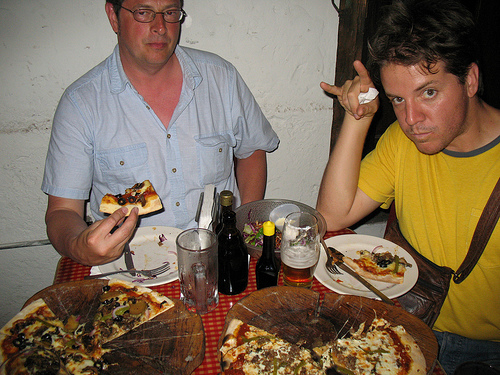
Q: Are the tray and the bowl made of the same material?
A: No, the tray is made of wood and the bowl is made of metal.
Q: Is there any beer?
A: Yes, there is beer.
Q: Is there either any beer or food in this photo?
A: Yes, there is beer.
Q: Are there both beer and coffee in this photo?
A: No, there is beer but no coffee.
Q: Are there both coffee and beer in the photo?
A: No, there is beer but no coffee.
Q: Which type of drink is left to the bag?
A: The drink is beer.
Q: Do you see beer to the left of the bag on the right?
A: Yes, there is beer to the left of the bag.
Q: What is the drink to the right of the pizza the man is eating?
A: The drink is beer.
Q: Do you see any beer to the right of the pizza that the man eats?
A: Yes, there is beer to the right of the pizza.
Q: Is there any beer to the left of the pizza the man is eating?
A: No, the beer is to the right of the pizza.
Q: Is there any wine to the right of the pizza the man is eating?
A: No, there is beer to the right of the pizza.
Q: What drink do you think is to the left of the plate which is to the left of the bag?
A: The drink is beer.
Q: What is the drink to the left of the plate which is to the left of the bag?
A: The drink is beer.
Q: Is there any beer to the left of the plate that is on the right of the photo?
A: Yes, there is beer to the left of the plate.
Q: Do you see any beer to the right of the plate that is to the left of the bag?
A: No, the beer is to the left of the plate.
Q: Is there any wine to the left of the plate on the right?
A: No, there is beer to the left of the plate.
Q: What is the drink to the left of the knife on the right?
A: The drink is beer.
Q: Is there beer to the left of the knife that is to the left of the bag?
A: Yes, there is beer to the left of the knife.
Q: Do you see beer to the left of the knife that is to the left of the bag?
A: Yes, there is beer to the left of the knife.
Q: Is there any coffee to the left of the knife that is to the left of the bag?
A: No, there is beer to the left of the knife.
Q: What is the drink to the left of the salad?
A: The drink is beer.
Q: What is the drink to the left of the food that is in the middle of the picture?
A: The drink is beer.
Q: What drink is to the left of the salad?
A: The drink is beer.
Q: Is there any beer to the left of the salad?
A: Yes, there is beer to the left of the salad.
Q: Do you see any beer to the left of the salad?
A: Yes, there is beer to the left of the salad.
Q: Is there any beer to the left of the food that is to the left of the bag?
A: Yes, there is beer to the left of the salad.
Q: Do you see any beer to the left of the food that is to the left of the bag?
A: Yes, there is beer to the left of the salad.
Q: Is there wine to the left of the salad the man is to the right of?
A: No, there is beer to the left of the salad.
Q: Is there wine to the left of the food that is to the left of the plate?
A: No, there is beer to the left of the salad.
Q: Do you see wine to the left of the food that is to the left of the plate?
A: No, there is beer to the left of the salad.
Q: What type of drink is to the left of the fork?
A: The drink is beer.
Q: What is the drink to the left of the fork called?
A: The drink is beer.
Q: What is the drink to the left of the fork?
A: The drink is beer.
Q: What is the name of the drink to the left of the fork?
A: The drink is beer.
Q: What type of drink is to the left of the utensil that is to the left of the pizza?
A: The drink is beer.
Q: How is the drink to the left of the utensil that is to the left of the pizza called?
A: The drink is beer.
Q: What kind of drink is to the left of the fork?
A: The drink is beer.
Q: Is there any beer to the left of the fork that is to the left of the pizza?
A: Yes, there is beer to the left of the fork.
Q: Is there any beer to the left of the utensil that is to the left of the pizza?
A: Yes, there is beer to the left of the fork.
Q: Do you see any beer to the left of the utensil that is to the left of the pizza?
A: Yes, there is beer to the left of the fork.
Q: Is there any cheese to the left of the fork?
A: No, there is beer to the left of the fork.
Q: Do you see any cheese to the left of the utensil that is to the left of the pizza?
A: No, there is beer to the left of the fork.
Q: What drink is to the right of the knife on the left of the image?
A: The drink is beer.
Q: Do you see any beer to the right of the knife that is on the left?
A: Yes, there is beer to the right of the knife.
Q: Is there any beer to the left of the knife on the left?
A: No, the beer is to the right of the knife.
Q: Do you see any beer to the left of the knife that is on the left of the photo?
A: No, the beer is to the right of the knife.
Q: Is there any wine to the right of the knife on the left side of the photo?
A: No, there is beer to the right of the knife.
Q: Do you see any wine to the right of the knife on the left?
A: No, there is beer to the right of the knife.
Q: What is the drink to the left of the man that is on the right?
A: The drink is beer.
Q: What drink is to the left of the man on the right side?
A: The drink is beer.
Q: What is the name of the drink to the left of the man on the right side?
A: The drink is beer.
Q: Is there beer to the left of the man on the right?
A: Yes, there is beer to the left of the man.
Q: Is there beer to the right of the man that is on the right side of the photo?
A: No, the beer is to the left of the man.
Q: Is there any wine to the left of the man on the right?
A: No, there is beer to the left of the man.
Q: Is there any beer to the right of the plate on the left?
A: Yes, there is beer to the right of the plate.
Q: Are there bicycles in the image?
A: No, there are no bicycles.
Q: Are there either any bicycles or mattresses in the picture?
A: No, there are no bicycles or mattresses.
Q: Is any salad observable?
A: Yes, there is salad.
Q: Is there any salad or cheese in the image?
A: Yes, there is salad.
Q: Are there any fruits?
A: No, there are no fruits.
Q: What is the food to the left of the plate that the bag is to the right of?
A: The food is salad.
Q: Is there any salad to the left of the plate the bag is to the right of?
A: Yes, there is salad to the left of the plate.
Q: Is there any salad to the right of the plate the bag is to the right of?
A: No, the salad is to the left of the plate.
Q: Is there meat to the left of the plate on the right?
A: No, there is salad to the left of the plate.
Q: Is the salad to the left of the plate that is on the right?
A: Yes, the salad is to the left of the plate.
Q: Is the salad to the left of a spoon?
A: No, the salad is to the left of the plate.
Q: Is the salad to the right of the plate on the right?
A: No, the salad is to the left of the plate.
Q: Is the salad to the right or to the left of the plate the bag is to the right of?
A: The salad is to the left of the plate.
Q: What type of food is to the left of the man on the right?
A: The food is salad.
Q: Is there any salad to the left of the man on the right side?
A: Yes, there is salad to the left of the man.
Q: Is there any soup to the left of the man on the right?
A: No, there is salad to the left of the man.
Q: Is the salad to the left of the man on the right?
A: Yes, the salad is to the left of the man.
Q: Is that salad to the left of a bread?
A: No, the salad is to the left of the man.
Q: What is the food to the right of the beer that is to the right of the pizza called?
A: The food is salad.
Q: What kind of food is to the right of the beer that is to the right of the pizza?
A: The food is salad.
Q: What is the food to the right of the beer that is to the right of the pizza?
A: The food is salad.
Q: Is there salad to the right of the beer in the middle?
A: Yes, there is salad to the right of the beer.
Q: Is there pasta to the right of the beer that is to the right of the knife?
A: No, there is salad to the right of the beer.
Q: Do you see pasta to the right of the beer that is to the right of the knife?
A: No, there is salad to the right of the beer.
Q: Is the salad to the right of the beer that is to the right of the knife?
A: Yes, the salad is to the right of the beer.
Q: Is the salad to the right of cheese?
A: No, the salad is to the right of the beer.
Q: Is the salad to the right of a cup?
A: No, the salad is to the right of the plate.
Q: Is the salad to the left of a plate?
A: No, the salad is to the right of a plate.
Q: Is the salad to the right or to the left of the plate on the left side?
A: The salad is to the right of the plate.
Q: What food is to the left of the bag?
A: The food is salad.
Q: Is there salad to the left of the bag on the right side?
A: Yes, there is salad to the left of the bag.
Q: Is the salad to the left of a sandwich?
A: No, the salad is to the left of the bag.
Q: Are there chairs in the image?
A: No, there are no chairs.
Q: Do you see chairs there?
A: No, there are no chairs.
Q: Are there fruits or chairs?
A: No, there are no chairs or fruits.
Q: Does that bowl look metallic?
A: Yes, the bowl is metallic.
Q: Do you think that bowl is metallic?
A: Yes, the bowl is metallic.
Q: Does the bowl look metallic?
A: Yes, the bowl is metallic.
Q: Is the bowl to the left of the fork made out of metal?
A: Yes, the bowl is made of metal.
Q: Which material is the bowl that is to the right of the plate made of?
A: The bowl is made of metal.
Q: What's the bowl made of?
A: The bowl is made of metal.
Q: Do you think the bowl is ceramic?
A: No, the bowl is metallic.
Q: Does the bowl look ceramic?
A: No, the bowl is metallic.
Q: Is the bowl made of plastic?
A: No, the bowl is made of metal.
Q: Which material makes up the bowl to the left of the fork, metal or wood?
A: The bowl is made of metal.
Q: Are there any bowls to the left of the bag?
A: Yes, there is a bowl to the left of the bag.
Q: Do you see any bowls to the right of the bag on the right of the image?
A: No, the bowl is to the left of the bag.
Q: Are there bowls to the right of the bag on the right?
A: No, the bowl is to the left of the bag.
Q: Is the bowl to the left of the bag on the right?
A: Yes, the bowl is to the left of the bag.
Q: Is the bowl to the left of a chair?
A: No, the bowl is to the left of the bag.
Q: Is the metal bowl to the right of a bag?
A: No, the bowl is to the left of a bag.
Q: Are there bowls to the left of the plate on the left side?
A: No, the bowl is to the right of the plate.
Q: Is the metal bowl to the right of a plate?
A: Yes, the bowl is to the right of a plate.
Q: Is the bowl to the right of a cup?
A: No, the bowl is to the right of a plate.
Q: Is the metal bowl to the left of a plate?
A: No, the bowl is to the right of a plate.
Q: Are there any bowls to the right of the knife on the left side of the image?
A: Yes, there is a bowl to the right of the knife.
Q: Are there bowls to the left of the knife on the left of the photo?
A: No, the bowl is to the right of the knife.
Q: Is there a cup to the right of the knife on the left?
A: No, there is a bowl to the right of the knife.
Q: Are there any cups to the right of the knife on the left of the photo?
A: No, there is a bowl to the right of the knife.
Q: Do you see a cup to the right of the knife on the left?
A: No, there is a bowl to the right of the knife.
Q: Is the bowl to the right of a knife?
A: Yes, the bowl is to the right of a knife.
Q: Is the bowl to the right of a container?
A: No, the bowl is to the right of a knife.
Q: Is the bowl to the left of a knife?
A: No, the bowl is to the right of a knife.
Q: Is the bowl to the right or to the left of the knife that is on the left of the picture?
A: The bowl is to the right of the knife.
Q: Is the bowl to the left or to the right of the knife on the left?
A: The bowl is to the right of the knife.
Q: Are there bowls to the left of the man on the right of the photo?
A: Yes, there is a bowl to the left of the man.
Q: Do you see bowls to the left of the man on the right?
A: Yes, there is a bowl to the left of the man.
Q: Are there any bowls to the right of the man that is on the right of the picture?
A: No, the bowl is to the left of the man.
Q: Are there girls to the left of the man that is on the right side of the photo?
A: No, there is a bowl to the left of the man.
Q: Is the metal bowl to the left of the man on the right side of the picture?
A: Yes, the bowl is to the left of the man.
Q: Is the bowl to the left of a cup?
A: No, the bowl is to the left of the man.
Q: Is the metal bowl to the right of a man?
A: No, the bowl is to the left of a man.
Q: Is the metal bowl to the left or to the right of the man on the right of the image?
A: The bowl is to the left of the man.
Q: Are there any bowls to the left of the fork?
A: Yes, there is a bowl to the left of the fork.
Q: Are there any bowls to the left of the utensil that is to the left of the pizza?
A: Yes, there is a bowl to the left of the fork.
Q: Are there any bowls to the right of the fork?
A: No, the bowl is to the left of the fork.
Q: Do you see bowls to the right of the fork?
A: No, the bowl is to the left of the fork.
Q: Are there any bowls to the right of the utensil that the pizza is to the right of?
A: No, the bowl is to the left of the fork.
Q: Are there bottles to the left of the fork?
A: No, there is a bowl to the left of the fork.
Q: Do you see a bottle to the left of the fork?
A: No, there is a bowl to the left of the fork.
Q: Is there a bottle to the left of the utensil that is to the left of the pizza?
A: No, there is a bowl to the left of the fork.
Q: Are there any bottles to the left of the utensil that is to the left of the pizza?
A: No, there is a bowl to the left of the fork.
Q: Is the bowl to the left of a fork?
A: Yes, the bowl is to the left of a fork.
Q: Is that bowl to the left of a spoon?
A: No, the bowl is to the left of a fork.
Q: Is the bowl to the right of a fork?
A: No, the bowl is to the left of a fork.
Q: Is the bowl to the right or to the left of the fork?
A: The bowl is to the left of the fork.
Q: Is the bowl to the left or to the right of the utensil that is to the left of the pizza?
A: The bowl is to the left of the fork.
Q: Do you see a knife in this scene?
A: Yes, there is a knife.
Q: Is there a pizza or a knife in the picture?
A: Yes, there is a knife.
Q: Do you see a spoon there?
A: No, there are no spoons.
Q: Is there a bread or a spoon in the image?
A: No, there are no spoons or breads.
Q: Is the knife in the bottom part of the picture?
A: Yes, the knife is in the bottom of the image.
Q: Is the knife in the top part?
A: No, the knife is in the bottom of the image.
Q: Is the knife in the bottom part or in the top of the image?
A: The knife is in the bottom of the image.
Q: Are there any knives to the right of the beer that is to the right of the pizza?
A: Yes, there is a knife to the right of the beer.